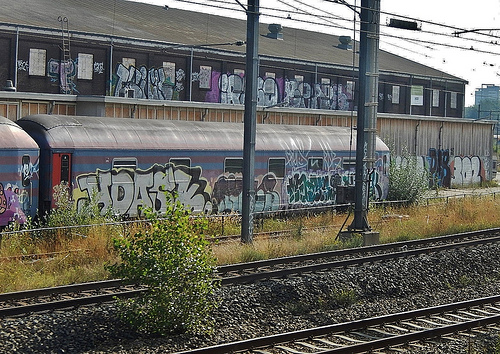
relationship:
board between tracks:
[414, 309, 444, 326] [23, 207, 473, 352]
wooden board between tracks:
[292, 340, 327, 350] [327, 299, 487, 351]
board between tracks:
[367, 327, 402, 336] [290, 299, 498, 352]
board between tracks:
[402, 318, 432, 331] [290, 299, 498, 352]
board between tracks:
[446, 310, 472, 319] [290, 299, 498, 352]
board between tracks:
[402, 318, 429, 328] [290, 299, 498, 352]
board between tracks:
[334, 334, 369, 341] [290, 299, 498, 352]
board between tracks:
[368, 322, 403, 340] [0, 217, 497, 348]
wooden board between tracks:
[383, 320, 427, 335] [0, 217, 497, 348]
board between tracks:
[467, 296, 499, 330] [0, 217, 497, 348]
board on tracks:
[32, 140, 74, 220] [72, 227, 498, 351]